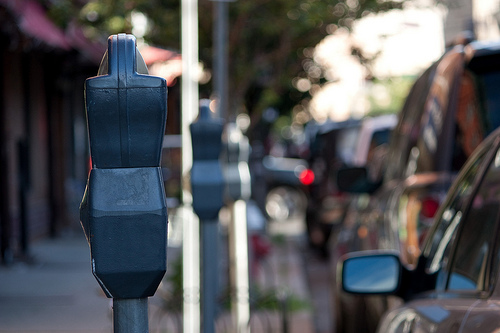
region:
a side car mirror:
[334, 252, 409, 294]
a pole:
[193, 212, 225, 332]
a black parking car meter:
[78, 33, 165, 331]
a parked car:
[338, 131, 497, 329]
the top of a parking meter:
[90, 29, 155, 82]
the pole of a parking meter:
[115, 295, 149, 332]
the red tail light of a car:
[295, 165, 316, 190]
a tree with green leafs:
[143, 0, 390, 128]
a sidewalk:
[0, 178, 207, 330]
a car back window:
[452, 145, 499, 303]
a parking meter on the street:
[62, 22, 197, 327]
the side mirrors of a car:
[335, 241, 432, 308]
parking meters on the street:
[179, 86, 237, 328]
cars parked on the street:
[290, 24, 498, 329]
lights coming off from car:
[294, 162, 320, 193]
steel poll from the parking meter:
[111, 297, 151, 330]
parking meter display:
[91, 29, 157, 88]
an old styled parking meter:
[78, 23, 173, 330]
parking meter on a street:
[222, 123, 263, 330]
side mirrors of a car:
[336, 159, 390, 200]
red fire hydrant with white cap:
[238, 199, 273, 286]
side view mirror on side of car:
[338, 243, 415, 303]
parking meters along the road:
[75, 34, 229, 331]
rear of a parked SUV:
[356, 31, 496, 316]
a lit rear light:
[296, 167, 320, 188]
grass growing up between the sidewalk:
[176, 280, 315, 318]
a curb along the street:
[271, 227, 314, 332]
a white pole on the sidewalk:
[177, 4, 204, 331]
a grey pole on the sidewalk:
[213, 2, 226, 332]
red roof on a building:
[1, 0, 101, 65]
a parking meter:
[78, 45, 178, 302]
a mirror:
[326, 255, 412, 294]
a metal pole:
[113, 305, 143, 331]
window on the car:
[448, 224, 484, 284]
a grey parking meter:
[191, 113, 231, 209]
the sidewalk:
[18, 270, 92, 323]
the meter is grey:
[88, 70, 162, 289]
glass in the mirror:
[346, 261, 403, 291]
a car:
[387, 87, 464, 201]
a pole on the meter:
[199, 222, 225, 332]